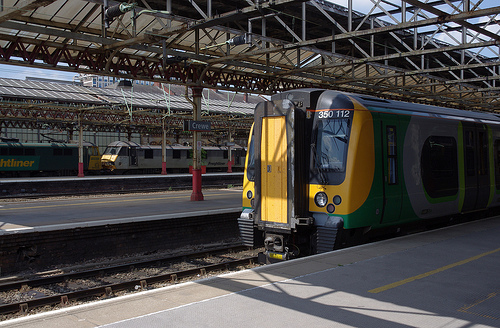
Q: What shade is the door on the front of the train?
A: Yellow.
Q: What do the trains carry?
A: Passengers?.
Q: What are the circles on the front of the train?
A: Lights.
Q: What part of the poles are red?
A: Bottom.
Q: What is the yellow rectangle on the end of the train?
A: Door.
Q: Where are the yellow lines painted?
A: Platform.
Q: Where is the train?
A: Train station.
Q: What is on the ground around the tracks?
A: Gravel.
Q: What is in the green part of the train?
A: Window.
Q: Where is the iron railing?
A: Roof.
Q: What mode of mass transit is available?
A: A train.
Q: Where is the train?
A: At the station.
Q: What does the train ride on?
A: The tracks.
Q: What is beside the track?
A: The platform.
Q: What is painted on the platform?
A: Yellow lines.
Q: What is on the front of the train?
A: Lights.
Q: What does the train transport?
A: Passengers.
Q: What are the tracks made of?
A: Steel.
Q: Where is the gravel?
A: On the tracks.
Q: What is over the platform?
A: An awning.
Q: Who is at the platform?
A: No one.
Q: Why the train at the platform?
A: To load and unload.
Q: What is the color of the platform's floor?
A: Gray.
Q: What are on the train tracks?
A: Trains.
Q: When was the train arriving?
A: Just now.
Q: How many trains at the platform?
A: Two.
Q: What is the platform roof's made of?
A: Steel.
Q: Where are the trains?
A: At the platform.